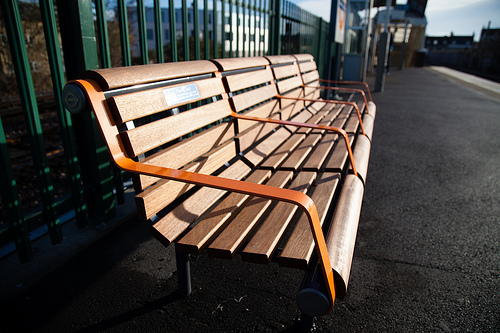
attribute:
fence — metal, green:
[81, 10, 266, 56]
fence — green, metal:
[62, 47, 372, 295]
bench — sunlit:
[55, 49, 417, 308]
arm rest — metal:
[192, 179, 305, 211]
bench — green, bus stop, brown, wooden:
[71, 40, 385, 310]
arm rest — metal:
[242, 182, 322, 225]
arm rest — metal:
[202, 166, 272, 205]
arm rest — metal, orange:
[144, 164, 289, 217]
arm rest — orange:
[71, 80, 340, 314]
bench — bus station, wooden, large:
[51, 47, 380, 305]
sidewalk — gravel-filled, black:
[318, 60, 496, 331]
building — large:
[119, 4, 276, 60]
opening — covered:
[372, 11, 411, 71]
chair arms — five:
[152, 80, 360, 298]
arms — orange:
[141, 79, 373, 299]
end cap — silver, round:
[296, 283, 334, 323]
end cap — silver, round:
[62, 83, 89, 118]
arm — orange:
[62, 72, 344, 323]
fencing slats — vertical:
[3, 0, 332, 263]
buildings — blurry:
[413, 17, 499, 80]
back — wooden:
[68, 59, 320, 216]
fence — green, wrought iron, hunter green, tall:
[4, 0, 328, 276]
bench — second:
[208, 55, 373, 193]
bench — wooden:
[62, 45, 381, 330]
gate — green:
[3, 2, 335, 255]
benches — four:
[75, 37, 399, 307]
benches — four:
[87, 45, 421, 309]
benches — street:
[63, 39, 413, 314]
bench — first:
[69, 60, 365, 327]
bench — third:
[270, 52, 370, 137]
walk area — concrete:
[0, 64, 497, 328]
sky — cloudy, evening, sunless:
[426, 1, 497, 39]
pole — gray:
[171, 242, 192, 292]